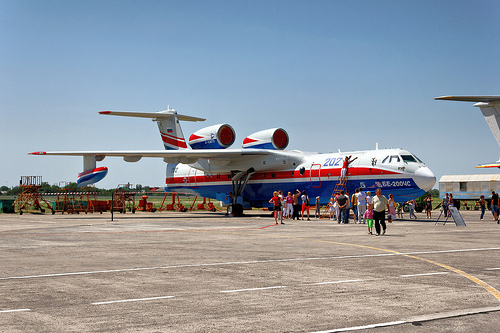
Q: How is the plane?
A: Large.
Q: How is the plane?
A: Red white and blue.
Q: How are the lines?
A: White.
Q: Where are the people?
A: Plane.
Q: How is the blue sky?
A: Clear.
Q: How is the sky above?
A: Clear.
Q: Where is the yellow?
A: Lines.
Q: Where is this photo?
A: Airfield.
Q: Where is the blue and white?
A: Plane.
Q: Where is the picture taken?
A: A tarmac.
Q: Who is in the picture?
A: Travellers.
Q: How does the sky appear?
A: Blue and clear.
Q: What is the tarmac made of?
A: Concrete.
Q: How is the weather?
A: Clear and sunny.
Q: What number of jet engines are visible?
A: Two.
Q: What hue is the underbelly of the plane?
A: Blue.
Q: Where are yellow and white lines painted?
A: The runway.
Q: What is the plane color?
A: Red.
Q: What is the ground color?
A: Gray.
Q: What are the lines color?
A: White.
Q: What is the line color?
A: Yellow.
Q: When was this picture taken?
A: Daytime.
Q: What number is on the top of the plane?
A: 202.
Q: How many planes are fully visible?
A: One.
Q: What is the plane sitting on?
A: Tarmac.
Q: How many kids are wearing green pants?
A: One.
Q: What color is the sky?
A: Blue.